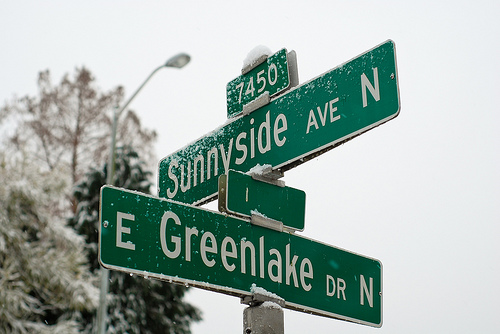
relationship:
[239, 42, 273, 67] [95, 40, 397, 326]
snow on street sign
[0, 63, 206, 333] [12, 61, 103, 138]
tree covered in leaves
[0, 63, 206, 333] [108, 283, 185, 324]
tree with leaves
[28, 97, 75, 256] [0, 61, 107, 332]
snow on trees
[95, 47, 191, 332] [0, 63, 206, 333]
light tall as tree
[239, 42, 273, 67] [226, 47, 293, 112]
snow on top of sign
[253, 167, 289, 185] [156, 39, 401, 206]
brackets on sign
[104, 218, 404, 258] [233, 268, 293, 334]
street sign on a post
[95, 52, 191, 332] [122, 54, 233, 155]
light on a post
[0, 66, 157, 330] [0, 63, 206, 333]
snow on tree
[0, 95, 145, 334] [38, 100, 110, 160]
snow on trees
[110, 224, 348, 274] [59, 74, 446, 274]
letters on street sign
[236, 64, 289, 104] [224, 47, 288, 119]
letter on street sign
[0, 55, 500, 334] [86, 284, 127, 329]
street light pole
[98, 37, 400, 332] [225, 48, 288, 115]
cluster of green metal street sign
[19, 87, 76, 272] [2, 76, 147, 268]
tree covered in brown leaves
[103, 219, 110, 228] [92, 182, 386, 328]
bolt on green metal street sign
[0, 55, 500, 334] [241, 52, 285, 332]
street sign on pole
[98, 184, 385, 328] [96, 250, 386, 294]
sign on bottom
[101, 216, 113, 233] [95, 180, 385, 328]
bolt on street sign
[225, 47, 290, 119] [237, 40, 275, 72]
sign covered in snow